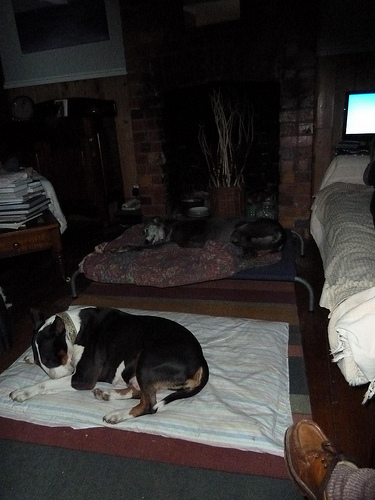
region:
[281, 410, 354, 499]
person wearing light brown leather shoe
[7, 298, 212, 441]
dog lying on the floor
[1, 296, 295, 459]
white blanket on the floor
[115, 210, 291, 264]
dog lying next to firepalce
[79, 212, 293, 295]
red patterned cushion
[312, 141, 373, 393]
white couch on the side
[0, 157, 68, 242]
stack of books and papers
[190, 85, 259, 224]
dead plant sitting in fireplace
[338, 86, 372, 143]
computer monitor on the side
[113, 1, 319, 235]
brick fireplace at the end of the room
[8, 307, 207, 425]
a white black and brown dog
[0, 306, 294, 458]
a white striped pad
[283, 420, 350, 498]
a brown leather shoe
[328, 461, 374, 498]
a grey striped sock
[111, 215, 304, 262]
a black and white sleeping dog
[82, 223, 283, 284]
a large pink pad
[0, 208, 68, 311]
a brown wood table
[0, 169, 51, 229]
a stack of books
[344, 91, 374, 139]
a small TV set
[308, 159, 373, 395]
a white covered couch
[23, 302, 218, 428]
large dog sleeping on a dog bed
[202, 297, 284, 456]
dog bed with stripes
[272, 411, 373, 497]
man's shoe with laces and socks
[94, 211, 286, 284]
very large dog sleeping on a floral dog bed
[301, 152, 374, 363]
part of a bed with white and grey bedding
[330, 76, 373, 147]
part of a flat screen television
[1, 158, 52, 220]
a pile of books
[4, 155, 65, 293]
a pile of books on a stool with a drawer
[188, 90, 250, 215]
decoration with tree branches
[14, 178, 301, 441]
two dogs sleeping on dog beds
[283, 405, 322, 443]
a mans dirty shoe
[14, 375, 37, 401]
a dogs white paw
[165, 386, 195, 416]
a dogs black tail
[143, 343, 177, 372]
a black and white dog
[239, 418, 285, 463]
a dog laying on a white pillow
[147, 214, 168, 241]
a big dog laying on a blanket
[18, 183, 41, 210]
a lot of books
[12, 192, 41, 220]
books laying on table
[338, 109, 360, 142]
a black television in the room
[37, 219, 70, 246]
a wooden table with books on it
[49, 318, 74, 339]
Dog has black ear.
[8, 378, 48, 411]
Dog has white paw.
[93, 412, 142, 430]
Dog has white black paw.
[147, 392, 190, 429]
Tip of dog's tail is white.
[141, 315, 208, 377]
Dog has black back.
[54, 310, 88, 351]
Dog wearing gray collar.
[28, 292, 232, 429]
Dog laying on white dog bed.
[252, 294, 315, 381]
Striped area rug in room.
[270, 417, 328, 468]
Person wearing brown shoe.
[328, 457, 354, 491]
Person wearing gray sock.